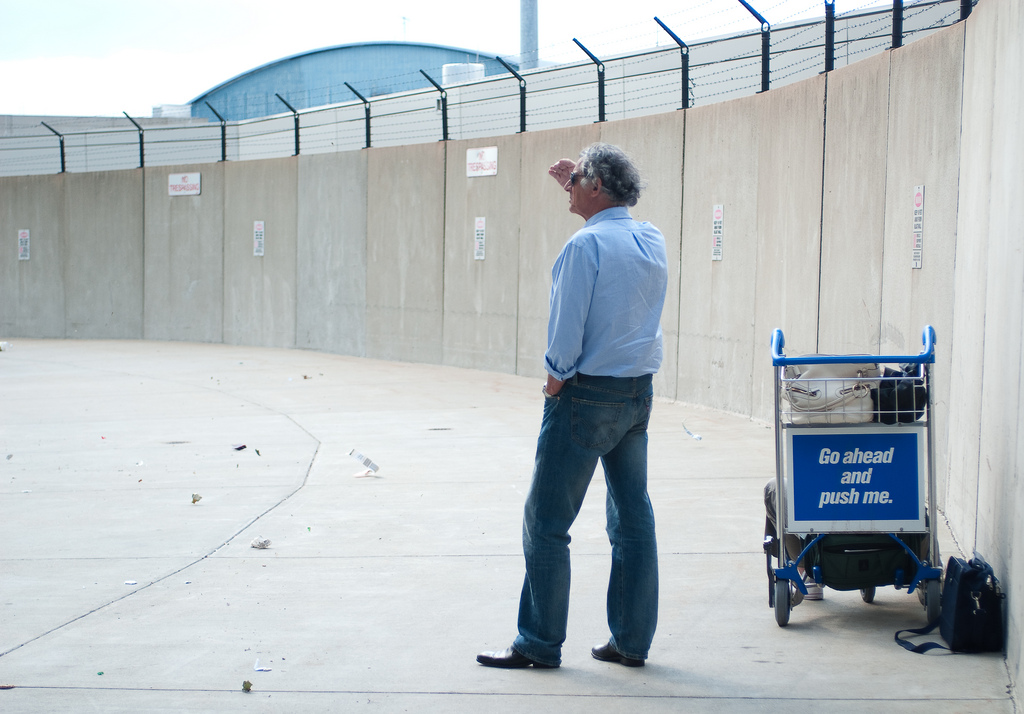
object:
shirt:
[544, 207, 668, 382]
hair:
[580, 143, 643, 207]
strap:
[895, 615, 952, 653]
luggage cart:
[762, 326, 937, 626]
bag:
[893, 550, 1002, 654]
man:
[473, 150, 673, 668]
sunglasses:
[570, 171, 587, 185]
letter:
[818, 447, 895, 507]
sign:
[781, 424, 926, 532]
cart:
[774, 328, 935, 422]